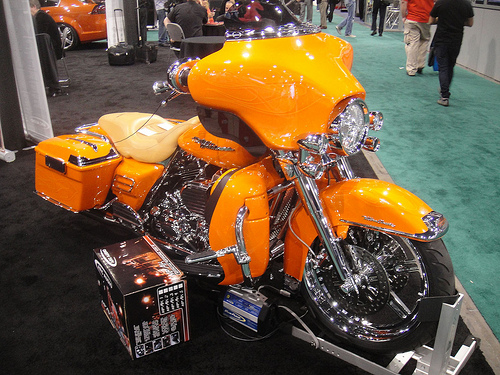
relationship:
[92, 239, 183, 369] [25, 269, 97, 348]
box on floor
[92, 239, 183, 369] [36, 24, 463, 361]
box beside motorcycle